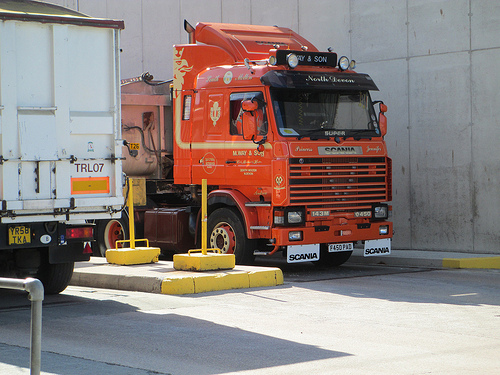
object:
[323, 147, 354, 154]
word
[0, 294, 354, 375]
shadow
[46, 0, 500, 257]
wall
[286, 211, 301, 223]
headlights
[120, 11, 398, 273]
truck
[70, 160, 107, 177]
trl07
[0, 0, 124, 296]
truck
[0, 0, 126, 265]
rear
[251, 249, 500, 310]
shadow